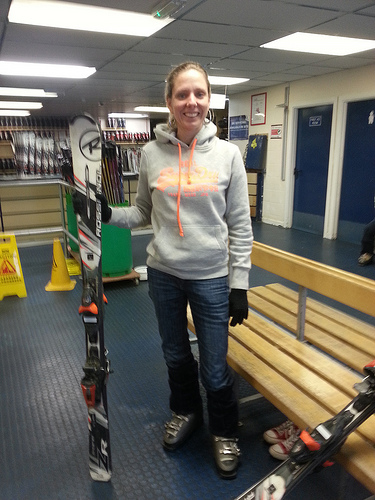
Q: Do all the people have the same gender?
A: Yes, all the people are female.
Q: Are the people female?
A: Yes, all the people are female.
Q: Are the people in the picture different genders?
A: No, all the people are female.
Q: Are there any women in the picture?
A: Yes, there are women.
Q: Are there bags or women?
A: Yes, there are women.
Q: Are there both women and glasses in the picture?
A: No, there are women but no glasses.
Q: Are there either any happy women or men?
A: Yes, there are happy women.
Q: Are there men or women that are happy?
A: Yes, the women are happy.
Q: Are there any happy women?
A: Yes, there are happy women.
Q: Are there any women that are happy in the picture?
A: Yes, there are happy women.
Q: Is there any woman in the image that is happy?
A: Yes, there are women that are happy.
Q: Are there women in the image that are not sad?
A: Yes, there are happy women.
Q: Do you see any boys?
A: No, there are no boys.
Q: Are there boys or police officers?
A: No, there are no boys or police officers.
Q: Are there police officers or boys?
A: No, there are no boys or police officers.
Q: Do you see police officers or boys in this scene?
A: No, there are no boys or police officers.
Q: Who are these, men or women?
A: These are women.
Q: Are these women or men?
A: These are women.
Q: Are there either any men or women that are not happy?
A: No, there are women but they are happy.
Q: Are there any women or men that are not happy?
A: No, there are women but they are happy.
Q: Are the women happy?
A: Yes, the women are happy.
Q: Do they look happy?
A: Yes, the women are happy.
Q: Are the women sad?
A: No, the women are happy.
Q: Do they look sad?
A: No, the women are happy.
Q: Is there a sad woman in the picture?
A: No, there are women but they are happy.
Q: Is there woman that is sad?
A: No, there are women but they are happy.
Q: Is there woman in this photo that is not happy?
A: No, there are women but they are happy.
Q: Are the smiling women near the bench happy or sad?
A: The women are happy.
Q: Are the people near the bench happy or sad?
A: The women are happy.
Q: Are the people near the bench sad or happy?
A: The women are happy.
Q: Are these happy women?
A: Yes, these are happy women.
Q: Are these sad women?
A: No, these are happy women.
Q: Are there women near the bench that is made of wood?
A: Yes, there are women near the bench.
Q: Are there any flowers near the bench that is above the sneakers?
A: No, there are women near the bench.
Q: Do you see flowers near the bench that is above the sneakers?
A: No, there are women near the bench.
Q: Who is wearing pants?
A: The women are wearing pants.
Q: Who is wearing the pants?
A: The women are wearing pants.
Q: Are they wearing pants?
A: Yes, the women are wearing pants.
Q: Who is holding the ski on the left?
A: The women are holding the ski.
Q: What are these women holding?
A: The women are holding the ski.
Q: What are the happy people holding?
A: The women are holding the ski.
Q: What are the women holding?
A: The women are holding the ski.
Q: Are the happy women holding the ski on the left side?
A: Yes, the women are holding the ski.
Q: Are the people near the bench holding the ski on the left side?
A: Yes, the women are holding the ski.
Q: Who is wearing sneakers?
A: The women are wearing sneakers.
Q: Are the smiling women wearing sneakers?
A: Yes, the women are wearing sneakers.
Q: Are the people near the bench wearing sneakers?
A: Yes, the women are wearing sneakers.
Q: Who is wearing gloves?
A: The women are wearing gloves.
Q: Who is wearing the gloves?
A: The women are wearing gloves.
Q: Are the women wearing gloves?
A: Yes, the women are wearing gloves.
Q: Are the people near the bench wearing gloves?
A: Yes, the women are wearing gloves.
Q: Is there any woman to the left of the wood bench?
A: Yes, there are women to the left of the bench.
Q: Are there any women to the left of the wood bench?
A: Yes, there are women to the left of the bench.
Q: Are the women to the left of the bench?
A: Yes, the women are to the left of the bench.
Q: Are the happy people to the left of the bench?
A: Yes, the women are to the left of the bench.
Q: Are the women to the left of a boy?
A: No, the women are to the left of the bench.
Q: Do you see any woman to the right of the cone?
A: Yes, there are women to the right of the cone.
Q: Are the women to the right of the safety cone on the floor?
A: Yes, the women are to the right of the safety cone.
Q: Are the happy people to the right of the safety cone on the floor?
A: Yes, the women are to the right of the safety cone.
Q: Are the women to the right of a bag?
A: No, the women are to the right of the safety cone.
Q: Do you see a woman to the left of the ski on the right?
A: Yes, there are women to the left of the ski.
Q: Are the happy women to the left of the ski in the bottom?
A: Yes, the women are to the left of the ski.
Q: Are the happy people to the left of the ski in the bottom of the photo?
A: Yes, the women are to the left of the ski.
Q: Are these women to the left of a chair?
A: No, the women are to the left of the ski.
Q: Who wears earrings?
A: The women wear earrings.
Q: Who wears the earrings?
A: The women wear earrings.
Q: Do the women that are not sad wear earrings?
A: Yes, the women wear earrings.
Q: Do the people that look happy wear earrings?
A: Yes, the women wear earrings.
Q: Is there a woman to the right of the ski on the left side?
A: Yes, there are women to the right of the ski.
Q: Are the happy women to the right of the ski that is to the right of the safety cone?
A: Yes, the women are to the right of the ski.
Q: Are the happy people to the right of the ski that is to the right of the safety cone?
A: Yes, the women are to the right of the ski.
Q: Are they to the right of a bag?
A: No, the women are to the right of the ski.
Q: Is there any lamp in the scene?
A: No, there are no lamps.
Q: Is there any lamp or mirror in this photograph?
A: No, there are no lamps or mirrors.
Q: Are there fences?
A: No, there are no fences.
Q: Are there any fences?
A: No, there are no fences.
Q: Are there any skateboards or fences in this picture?
A: No, there are no fences or skateboards.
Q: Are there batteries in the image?
A: No, there are no batteries.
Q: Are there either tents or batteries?
A: No, there are no batteries or tents.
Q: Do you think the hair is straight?
A: Yes, the hair is straight.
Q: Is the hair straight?
A: Yes, the hair is straight.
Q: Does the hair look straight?
A: Yes, the hair is straight.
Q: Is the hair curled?
A: No, the hair is straight.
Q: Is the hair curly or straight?
A: The hair is straight.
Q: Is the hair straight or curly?
A: The hair is straight.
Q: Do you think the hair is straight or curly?
A: The hair is straight.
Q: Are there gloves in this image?
A: Yes, there are gloves.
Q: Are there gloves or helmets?
A: Yes, there are gloves.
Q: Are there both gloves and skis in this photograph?
A: Yes, there are both gloves and a ski.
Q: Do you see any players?
A: No, there are no players.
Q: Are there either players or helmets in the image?
A: No, there are no players or helmets.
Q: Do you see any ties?
A: Yes, there is a tie.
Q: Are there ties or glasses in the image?
A: Yes, there is a tie.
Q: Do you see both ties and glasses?
A: No, there is a tie but no glasses.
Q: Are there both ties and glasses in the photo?
A: No, there is a tie but no glasses.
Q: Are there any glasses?
A: No, there are no glasses.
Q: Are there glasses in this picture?
A: No, there are no glasses.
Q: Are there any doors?
A: Yes, there is a door.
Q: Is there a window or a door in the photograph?
A: Yes, there is a door.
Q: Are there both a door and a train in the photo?
A: No, there is a door but no trains.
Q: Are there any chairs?
A: No, there are no chairs.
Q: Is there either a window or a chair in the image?
A: No, there are no chairs or windows.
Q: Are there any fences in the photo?
A: No, there are no fences.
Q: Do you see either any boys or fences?
A: No, there are no fences or boys.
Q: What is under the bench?
A: The sneakers are under the bench.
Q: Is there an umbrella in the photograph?
A: No, there are no umbrellas.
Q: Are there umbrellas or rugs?
A: No, there are no umbrellas or rugs.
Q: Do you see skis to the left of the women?
A: Yes, there is a ski to the left of the women.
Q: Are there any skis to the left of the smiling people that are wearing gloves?
A: Yes, there is a ski to the left of the women.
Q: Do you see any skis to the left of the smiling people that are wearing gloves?
A: Yes, there is a ski to the left of the women.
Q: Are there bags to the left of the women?
A: No, there is a ski to the left of the women.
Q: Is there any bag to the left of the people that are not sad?
A: No, there is a ski to the left of the women.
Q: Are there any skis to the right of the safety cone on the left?
A: Yes, there is a ski to the right of the traffic cone.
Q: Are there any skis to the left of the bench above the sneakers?
A: Yes, there is a ski to the left of the bench.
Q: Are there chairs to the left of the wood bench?
A: No, there is a ski to the left of the bench.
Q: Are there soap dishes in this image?
A: No, there are no soap dishes.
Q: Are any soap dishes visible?
A: No, there are no soap dishes.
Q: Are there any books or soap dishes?
A: No, there are no soap dishes or books.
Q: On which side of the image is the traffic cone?
A: The traffic cone is on the left of the image.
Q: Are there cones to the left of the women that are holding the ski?
A: Yes, there is a cone to the left of the women.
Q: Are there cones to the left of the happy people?
A: Yes, there is a cone to the left of the women.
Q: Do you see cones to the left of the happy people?
A: Yes, there is a cone to the left of the women.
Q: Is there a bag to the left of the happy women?
A: No, there is a cone to the left of the women.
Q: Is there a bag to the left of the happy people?
A: No, there is a cone to the left of the women.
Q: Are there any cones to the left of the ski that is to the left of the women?
A: Yes, there is a cone to the left of the ski.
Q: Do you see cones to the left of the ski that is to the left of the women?
A: Yes, there is a cone to the left of the ski.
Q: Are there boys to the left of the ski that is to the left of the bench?
A: No, there is a cone to the left of the ski.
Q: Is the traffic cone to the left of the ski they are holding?
A: Yes, the traffic cone is to the left of the ski.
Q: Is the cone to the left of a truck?
A: No, the cone is to the left of the ski.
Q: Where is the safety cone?
A: The safety cone is on the floor.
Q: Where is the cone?
A: The safety cone is on the floor.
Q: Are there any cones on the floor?
A: Yes, there is a cone on the floor.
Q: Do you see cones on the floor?
A: Yes, there is a cone on the floor.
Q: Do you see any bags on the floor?
A: No, there is a cone on the floor.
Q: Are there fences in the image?
A: No, there are no fences.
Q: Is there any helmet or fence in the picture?
A: No, there are no fences or helmets.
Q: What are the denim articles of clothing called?
A: The clothing items are pants.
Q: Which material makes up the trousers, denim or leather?
A: The trousers are made of denim.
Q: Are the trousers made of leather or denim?
A: The trousers are made of denim.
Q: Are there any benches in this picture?
A: Yes, there is a bench.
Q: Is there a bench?
A: Yes, there is a bench.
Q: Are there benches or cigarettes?
A: Yes, there is a bench.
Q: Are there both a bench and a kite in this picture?
A: No, there is a bench but no kites.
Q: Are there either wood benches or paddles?
A: Yes, there is a wood bench.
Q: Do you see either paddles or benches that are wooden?
A: Yes, the bench is wooden.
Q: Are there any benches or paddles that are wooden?
A: Yes, the bench is wooden.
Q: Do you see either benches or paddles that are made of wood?
A: Yes, the bench is made of wood.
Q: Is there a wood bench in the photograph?
A: Yes, there is a wood bench.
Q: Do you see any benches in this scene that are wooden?
A: Yes, there is a bench that is wooden.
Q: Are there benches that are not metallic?
A: Yes, there is a wooden bench.